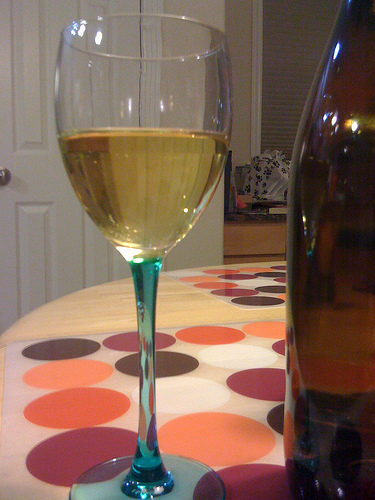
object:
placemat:
[3, 318, 298, 498]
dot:
[116, 349, 199, 377]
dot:
[20, 335, 101, 359]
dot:
[227, 366, 290, 401]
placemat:
[163, 264, 289, 309]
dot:
[201, 268, 238, 274]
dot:
[255, 284, 289, 294]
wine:
[54, 126, 230, 249]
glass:
[53, 12, 232, 500]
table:
[0, 259, 373, 497]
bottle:
[283, 1, 374, 499]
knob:
[0, 171, 13, 186]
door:
[0, 0, 138, 336]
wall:
[160, 0, 225, 270]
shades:
[261, 0, 352, 155]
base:
[66, 452, 227, 499]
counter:
[222, 211, 286, 223]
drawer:
[222, 224, 287, 256]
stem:
[131, 262, 159, 481]